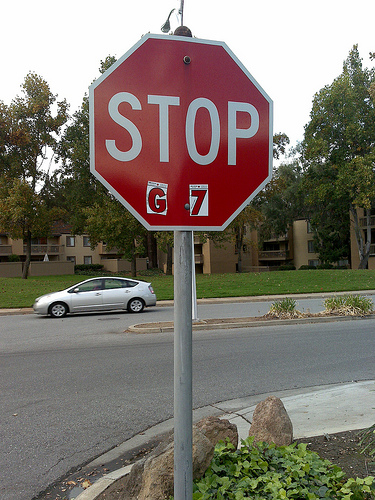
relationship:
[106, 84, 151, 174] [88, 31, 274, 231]
s on sign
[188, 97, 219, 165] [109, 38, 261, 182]
letter on sign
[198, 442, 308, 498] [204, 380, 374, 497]
leaves on ground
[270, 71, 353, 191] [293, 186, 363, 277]
trees in front on building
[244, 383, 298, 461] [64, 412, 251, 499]
rock next curve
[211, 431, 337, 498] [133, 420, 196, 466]
bush on curb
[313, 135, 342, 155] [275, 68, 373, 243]
green leaves on trees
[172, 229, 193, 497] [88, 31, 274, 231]
pole holding sign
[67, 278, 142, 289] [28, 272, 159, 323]
windows on car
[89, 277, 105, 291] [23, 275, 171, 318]
person drives car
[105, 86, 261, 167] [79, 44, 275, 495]
stop written on sign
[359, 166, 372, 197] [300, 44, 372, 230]
leaves are on tree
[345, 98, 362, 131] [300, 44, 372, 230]
leaves are on tree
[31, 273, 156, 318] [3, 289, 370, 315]
car parked on curb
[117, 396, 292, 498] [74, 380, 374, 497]
rocks on curb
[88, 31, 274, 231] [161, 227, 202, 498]
sign on pole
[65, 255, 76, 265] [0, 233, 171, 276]
window on apartment building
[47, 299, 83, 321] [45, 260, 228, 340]
rims on car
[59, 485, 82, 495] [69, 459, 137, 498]
water puddle on curb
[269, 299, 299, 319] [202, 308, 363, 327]
bush on ground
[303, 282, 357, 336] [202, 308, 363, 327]
bush on ground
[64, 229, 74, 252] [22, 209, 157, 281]
window on building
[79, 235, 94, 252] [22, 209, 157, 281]
window on building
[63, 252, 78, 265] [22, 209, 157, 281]
window on building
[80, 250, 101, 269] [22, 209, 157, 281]
window on building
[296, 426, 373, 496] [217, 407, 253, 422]
dirt near curb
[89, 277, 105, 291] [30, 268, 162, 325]
person driving car